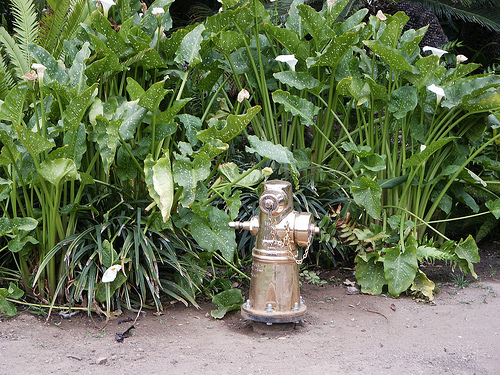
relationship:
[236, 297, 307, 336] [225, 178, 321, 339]
bottom belonging to hydrant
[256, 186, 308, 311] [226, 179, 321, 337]
side of a fire hydrant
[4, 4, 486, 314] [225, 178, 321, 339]
leaves behind a hydrant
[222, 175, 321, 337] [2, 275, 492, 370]
fire hydrant on dirt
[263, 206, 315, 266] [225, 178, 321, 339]
chain on hydrant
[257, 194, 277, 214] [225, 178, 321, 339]
nut on hydrant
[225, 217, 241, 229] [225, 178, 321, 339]
nut on hydrant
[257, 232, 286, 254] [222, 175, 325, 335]
stamp on hydrant